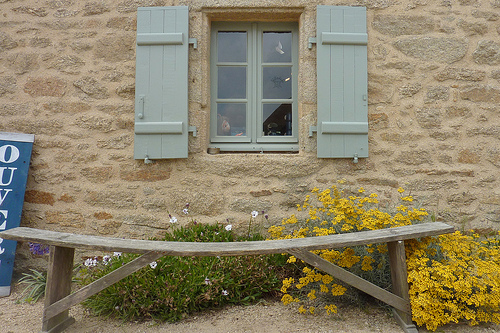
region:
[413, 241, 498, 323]
yellow flowers on the ground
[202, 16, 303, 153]
a window on a house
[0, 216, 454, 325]
a gray wooden bench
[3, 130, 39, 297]
a blue and white sign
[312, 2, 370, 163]
gray shutters on a wall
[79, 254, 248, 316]
purple and white flower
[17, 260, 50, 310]
long leafy grass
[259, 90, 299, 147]
a shadow in the window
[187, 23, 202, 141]
hinges on a shutter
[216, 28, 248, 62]
a pane of glass in a window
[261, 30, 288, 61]
a pane of glass in a window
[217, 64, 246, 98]
a pane of glass in a window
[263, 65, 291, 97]
a pane of glass in a window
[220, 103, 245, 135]
a pane of glass in a window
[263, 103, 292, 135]
a broken pane of glass in a window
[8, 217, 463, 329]
a wooden bench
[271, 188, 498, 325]
the yellow blooms of a plant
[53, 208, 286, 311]
the green foliage and white flowers of a plant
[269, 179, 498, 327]
Yellow flowers on the ground.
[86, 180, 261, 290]
White flowers on the ground.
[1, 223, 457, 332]
An old bench.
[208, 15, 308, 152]
Window with grey frame.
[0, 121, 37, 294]
A sign leaning against the wall.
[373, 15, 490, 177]
Wall made of rocks.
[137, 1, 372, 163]
Grey window shutters.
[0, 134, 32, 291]
White and blue sign.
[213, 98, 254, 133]
A teddy bear at the window.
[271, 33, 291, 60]
Lamps hanging from ceiling inside the house.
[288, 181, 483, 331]
Flowers next to the building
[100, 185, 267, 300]
Flowers next to the building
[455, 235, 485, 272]
Flowers next to the building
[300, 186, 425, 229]
Flowers next to the building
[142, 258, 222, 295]
Flowers next to the building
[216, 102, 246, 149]
child in a window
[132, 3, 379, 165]
shutters on a window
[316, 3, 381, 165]
green shutter on building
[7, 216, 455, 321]
bench in front of the building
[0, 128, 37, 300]
blue sign leaning on the wall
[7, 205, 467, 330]
long grey wooden bench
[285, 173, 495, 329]
yellow flowers near a bench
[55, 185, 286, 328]
few white flowers near bench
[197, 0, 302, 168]
six small windows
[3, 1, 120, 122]
sandy brown stoned wall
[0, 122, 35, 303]
blue and white sign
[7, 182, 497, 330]
flowers behind the bench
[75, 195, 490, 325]
white and yellow flowers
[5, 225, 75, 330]
purple flower with leaves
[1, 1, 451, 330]
bench below a window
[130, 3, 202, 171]
A gray wooden shutter by the window.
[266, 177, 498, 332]
Two yellow flowered bushes.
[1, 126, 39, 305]
Part of a blue sign.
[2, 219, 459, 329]
A long wooden bench.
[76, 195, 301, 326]
A green flower bush with white flowers.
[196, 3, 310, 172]
A window looking to the inside of the building.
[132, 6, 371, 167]
two green window shutters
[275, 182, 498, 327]
yellow flowers against a stone wall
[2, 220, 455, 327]
brown wooden bench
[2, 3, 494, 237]
building made ofstone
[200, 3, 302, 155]
window with green trim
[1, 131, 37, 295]
blue and white sign